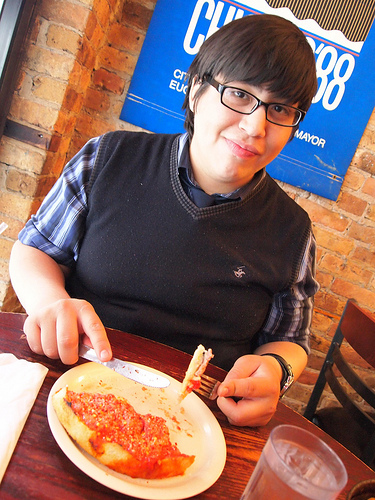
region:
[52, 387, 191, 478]
part of a piece of pizza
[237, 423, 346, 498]
a clear plastic glass of water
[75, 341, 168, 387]
a silver knife utensil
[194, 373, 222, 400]
a silver fork utensil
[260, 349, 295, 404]
a black band wrist watch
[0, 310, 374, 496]
a dark brown round table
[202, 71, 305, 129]
a pair of black eyeglasses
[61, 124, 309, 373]
a black vest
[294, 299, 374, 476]
a wood and metal restaurant chair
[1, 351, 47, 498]
a white napkin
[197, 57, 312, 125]
woman is wearing glasses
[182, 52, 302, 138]
the glasses are black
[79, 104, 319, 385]
woman's vest is black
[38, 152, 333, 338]
woman's shirt is plaid patterned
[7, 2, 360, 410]
woman is about to eat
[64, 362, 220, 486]
red food on plate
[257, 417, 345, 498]
water in the cup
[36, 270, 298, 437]
woman holding for and knife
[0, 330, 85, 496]
napkin next to plate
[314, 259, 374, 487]
brown chair behind woman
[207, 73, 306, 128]
the lady is wearing black rimmed glasses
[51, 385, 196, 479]
a pizza on a dinner plate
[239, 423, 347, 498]
a plastic glass of water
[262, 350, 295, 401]
a wrist watch on the lady's wrist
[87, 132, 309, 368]
a grey sweater vest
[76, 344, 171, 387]
a silver dinner knife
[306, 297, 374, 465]
a wooden dinner chair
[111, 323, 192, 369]
a wooden restaurant table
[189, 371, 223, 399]
a dinner fork in the left hand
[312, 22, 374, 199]
an advertising banner on the wall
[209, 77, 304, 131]
The black eyeglasses the person is wearing.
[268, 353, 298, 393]
The watch the person is wearing.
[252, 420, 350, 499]
The clear cup filled with water.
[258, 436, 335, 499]
The water in the clear cup.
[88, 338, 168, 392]
The butter knife in the person's hand.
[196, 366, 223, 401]
The fork in the person's hand.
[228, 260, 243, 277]
The white emblem on the person's vest.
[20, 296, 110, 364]
The person's left hand.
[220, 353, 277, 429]
The person's right hand.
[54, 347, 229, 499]
The white plate the food is on.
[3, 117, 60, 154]
A brick in a wall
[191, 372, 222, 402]
The end of a fork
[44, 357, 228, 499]
A plate of partially eaten pizza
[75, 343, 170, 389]
A silver cutting knife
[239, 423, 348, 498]
A glass of ice water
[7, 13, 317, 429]
A girl eating pizza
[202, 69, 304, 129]
A pair of black framed glasses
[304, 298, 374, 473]
Part of a wooden dining chair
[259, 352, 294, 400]
A wrist watch on someone's wrist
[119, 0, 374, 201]
Part of a political poster